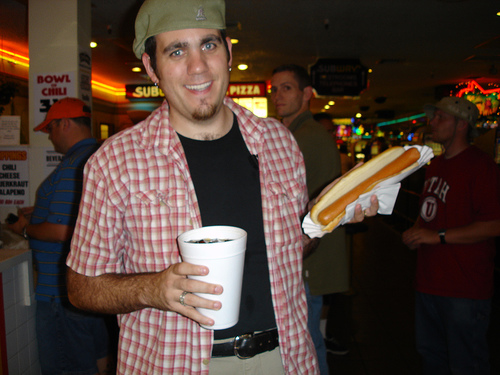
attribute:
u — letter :
[134, 82, 152, 99]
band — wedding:
[165, 282, 201, 309]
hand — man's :
[149, 255, 222, 330]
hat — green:
[121, 8, 238, 46]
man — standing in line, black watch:
[63, 5, 435, 360]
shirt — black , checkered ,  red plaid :
[70, 107, 327, 368]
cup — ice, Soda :
[178, 222, 260, 325]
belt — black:
[204, 329, 283, 359]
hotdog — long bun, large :
[306, 130, 435, 236]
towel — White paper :
[356, 190, 396, 216]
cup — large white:
[176, 227, 255, 330]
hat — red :
[34, 84, 85, 138]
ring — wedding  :
[171, 288, 191, 304]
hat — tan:
[124, 6, 238, 50]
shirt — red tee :
[416, 150, 484, 280]